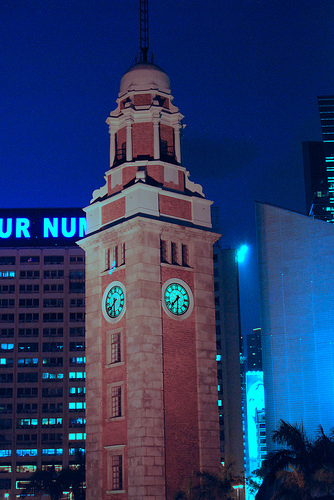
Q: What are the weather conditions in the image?
A: It is clear.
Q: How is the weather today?
A: It is clear.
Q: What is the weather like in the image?
A: It is clear.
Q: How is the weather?
A: It is clear.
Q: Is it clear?
A: Yes, it is clear.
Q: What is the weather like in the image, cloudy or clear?
A: It is clear.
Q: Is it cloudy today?
A: No, it is clear.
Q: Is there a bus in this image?
A: No, there are no buses.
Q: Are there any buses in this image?
A: No, there are no buses.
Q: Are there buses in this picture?
A: No, there are no buses.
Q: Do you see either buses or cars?
A: No, there are no buses or cars.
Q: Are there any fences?
A: No, there are no fences.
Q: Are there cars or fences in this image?
A: No, there are no fences or cars.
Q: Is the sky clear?
A: Yes, the sky is clear.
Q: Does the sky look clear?
A: Yes, the sky is clear.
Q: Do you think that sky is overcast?
A: No, the sky is clear.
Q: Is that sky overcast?
A: No, the sky is clear.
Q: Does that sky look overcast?
A: No, the sky is clear.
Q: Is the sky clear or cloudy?
A: The sky is clear.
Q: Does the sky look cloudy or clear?
A: The sky is clear.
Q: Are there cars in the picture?
A: No, there are no cars.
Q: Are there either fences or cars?
A: No, there are no cars or fences.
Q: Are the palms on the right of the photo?
A: Yes, the palms are on the right of the image.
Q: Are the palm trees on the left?
A: No, the palm trees are on the right of the image.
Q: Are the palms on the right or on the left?
A: The palms are on the right of the image.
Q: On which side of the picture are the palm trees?
A: The palm trees are on the right of the image.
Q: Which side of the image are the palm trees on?
A: The palm trees are on the right of the image.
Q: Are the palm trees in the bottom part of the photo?
A: Yes, the palm trees are in the bottom of the image.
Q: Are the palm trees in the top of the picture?
A: No, the palm trees are in the bottom of the image.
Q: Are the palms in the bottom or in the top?
A: The palms are in the bottom of the image.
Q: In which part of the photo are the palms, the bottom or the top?
A: The palms are in the bottom of the image.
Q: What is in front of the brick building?
A: The palms are in front of the building.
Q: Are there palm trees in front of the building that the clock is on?
A: Yes, there are palm trees in front of the building.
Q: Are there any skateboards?
A: No, there are no skateboards.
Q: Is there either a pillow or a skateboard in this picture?
A: No, there are no skateboards or pillows.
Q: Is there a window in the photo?
A: Yes, there is a window.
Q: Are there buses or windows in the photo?
A: Yes, there is a window.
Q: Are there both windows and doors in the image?
A: No, there is a window but no doors.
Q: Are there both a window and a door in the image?
A: No, there is a window but no doors.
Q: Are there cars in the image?
A: No, there are no cars.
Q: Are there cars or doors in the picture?
A: No, there are no cars or doors.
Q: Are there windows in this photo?
A: Yes, there is a window.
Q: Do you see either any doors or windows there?
A: Yes, there is a window.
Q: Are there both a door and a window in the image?
A: No, there is a window but no doors.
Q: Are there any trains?
A: No, there are no trains.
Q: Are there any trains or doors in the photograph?
A: No, there are no trains or doors.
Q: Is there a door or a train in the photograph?
A: No, there are no trains or doors.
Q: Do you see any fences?
A: No, there are no fences.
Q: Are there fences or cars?
A: No, there are no fences or cars.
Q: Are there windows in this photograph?
A: Yes, there is a window.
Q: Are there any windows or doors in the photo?
A: Yes, there is a window.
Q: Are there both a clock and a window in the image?
A: Yes, there are both a window and a clock.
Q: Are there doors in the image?
A: No, there are no doors.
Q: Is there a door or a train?
A: No, there are no doors or trains.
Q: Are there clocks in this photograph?
A: Yes, there is a clock.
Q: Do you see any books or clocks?
A: Yes, there is a clock.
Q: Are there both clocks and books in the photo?
A: No, there is a clock but no books.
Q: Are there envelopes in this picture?
A: No, there are no envelopes.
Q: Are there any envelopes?
A: No, there are no envelopes.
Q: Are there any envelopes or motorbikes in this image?
A: No, there are no envelopes or motorbikes.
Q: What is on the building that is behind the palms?
A: The clock is on the building.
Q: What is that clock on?
A: The clock is on the building.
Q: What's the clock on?
A: The clock is on the building.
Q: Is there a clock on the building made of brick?
A: Yes, there is a clock on the building.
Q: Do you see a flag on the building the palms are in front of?
A: No, there is a clock on the building.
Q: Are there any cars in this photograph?
A: No, there are no cars.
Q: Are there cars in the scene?
A: No, there are no cars.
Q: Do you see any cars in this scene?
A: No, there are no cars.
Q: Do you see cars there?
A: No, there are no cars.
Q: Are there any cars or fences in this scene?
A: No, there are no cars or fences.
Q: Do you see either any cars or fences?
A: No, there are no cars or fences.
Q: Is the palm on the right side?
A: Yes, the palm is on the right of the image.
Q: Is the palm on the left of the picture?
A: No, the palm is on the right of the image.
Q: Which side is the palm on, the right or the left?
A: The palm is on the right of the image.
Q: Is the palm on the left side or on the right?
A: The palm is on the right of the image.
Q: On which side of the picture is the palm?
A: The palm is on the right of the image.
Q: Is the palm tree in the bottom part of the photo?
A: Yes, the palm tree is in the bottom of the image.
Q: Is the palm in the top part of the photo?
A: No, the palm is in the bottom of the image.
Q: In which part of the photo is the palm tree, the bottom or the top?
A: The palm tree is in the bottom of the image.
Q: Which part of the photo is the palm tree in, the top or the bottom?
A: The palm tree is in the bottom of the image.